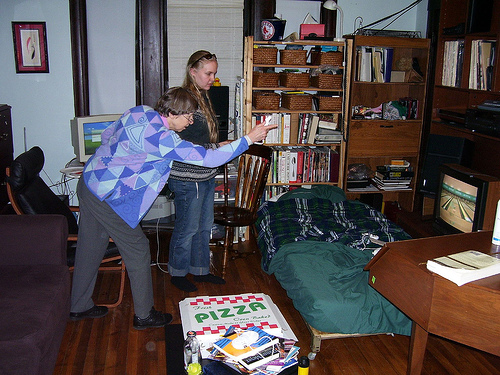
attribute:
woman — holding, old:
[73, 89, 277, 313]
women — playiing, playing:
[103, 90, 266, 195]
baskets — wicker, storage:
[262, 35, 322, 98]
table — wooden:
[378, 227, 424, 291]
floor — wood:
[73, 320, 162, 375]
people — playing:
[115, 45, 326, 301]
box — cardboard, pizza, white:
[182, 275, 332, 351]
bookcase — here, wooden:
[230, 39, 391, 162]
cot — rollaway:
[277, 184, 381, 336]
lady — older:
[99, 75, 148, 168]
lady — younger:
[156, 48, 235, 117]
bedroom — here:
[79, 49, 418, 328]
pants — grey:
[73, 226, 176, 309]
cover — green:
[296, 249, 358, 303]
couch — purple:
[13, 210, 87, 342]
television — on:
[431, 153, 490, 226]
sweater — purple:
[115, 121, 168, 193]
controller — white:
[242, 93, 286, 142]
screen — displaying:
[430, 147, 472, 223]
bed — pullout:
[269, 208, 392, 359]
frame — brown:
[34, 14, 62, 100]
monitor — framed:
[68, 107, 137, 161]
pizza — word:
[199, 289, 265, 311]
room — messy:
[2, 2, 494, 367]